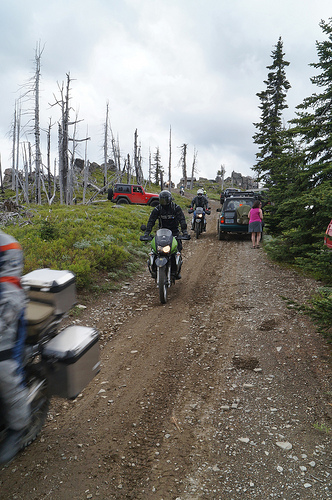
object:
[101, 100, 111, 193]
trees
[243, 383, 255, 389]
rocks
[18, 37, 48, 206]
tree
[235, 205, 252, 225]
tire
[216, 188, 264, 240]
vehicle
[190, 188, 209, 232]
man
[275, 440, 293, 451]
stone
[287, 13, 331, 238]
pine tree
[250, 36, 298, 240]
pine tree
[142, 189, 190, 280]
man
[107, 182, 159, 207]
jeep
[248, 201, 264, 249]
woman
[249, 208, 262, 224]
shirt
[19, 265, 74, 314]
container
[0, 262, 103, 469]
vehicle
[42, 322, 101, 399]
container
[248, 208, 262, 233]
clothes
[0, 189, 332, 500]
dirt road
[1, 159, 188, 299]
grass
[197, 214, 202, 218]
light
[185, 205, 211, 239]
bike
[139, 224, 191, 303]
bike